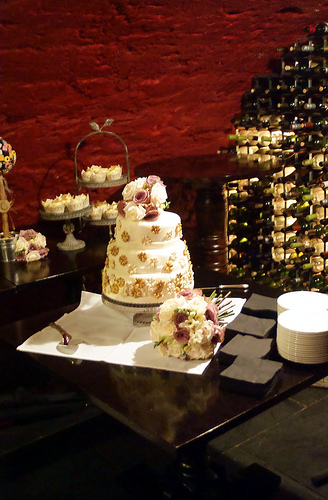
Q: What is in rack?
A: Wine.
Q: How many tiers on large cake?
A: Three.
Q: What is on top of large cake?
A: Flowers.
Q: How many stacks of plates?
A: Two.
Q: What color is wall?
A: Red.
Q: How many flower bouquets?
A: Four.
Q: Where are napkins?
A: On table.